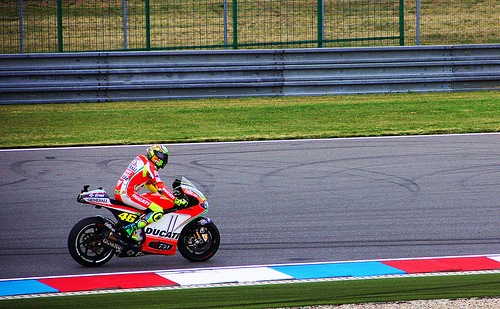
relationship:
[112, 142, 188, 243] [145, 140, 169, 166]
motorcyclist wearing helmet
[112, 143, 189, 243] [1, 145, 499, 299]
racer riding on raceway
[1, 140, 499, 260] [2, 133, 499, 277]
tire marks on track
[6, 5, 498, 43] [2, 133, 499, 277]
fence next to track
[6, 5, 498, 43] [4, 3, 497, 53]
fence next to field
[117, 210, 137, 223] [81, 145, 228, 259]
number on motorcycle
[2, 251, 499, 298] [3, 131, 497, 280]
buffer next to racetrack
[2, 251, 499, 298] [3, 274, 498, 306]
buffer next to infield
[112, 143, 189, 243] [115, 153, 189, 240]
racer dressed in clothing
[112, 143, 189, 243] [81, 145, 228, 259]
racer on motorcycle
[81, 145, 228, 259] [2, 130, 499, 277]
motorcycle heading down straightaway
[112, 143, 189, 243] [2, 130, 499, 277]
racer heading down straightaway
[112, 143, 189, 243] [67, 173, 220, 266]
racer riding bike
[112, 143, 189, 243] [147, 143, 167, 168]
racer wearing helmet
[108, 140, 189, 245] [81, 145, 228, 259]
man riding a motorcycle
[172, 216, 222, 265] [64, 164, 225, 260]
front wheel of motorcycle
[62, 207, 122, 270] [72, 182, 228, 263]
rear wheel of motorcycle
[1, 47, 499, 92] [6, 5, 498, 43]
guardrail next to fence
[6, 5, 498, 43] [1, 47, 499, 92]
fence in back of guardrail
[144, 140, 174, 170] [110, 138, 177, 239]
helmet worn by motorcyclist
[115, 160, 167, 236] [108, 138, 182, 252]
outfit worn by man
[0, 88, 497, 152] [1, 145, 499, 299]
grass on side of raceway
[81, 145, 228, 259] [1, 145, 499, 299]
motorcycle runs on a raceway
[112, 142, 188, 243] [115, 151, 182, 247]
motorcyclist wears suit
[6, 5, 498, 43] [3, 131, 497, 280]
fence beside racetrack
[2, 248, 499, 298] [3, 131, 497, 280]
line on side of racetrack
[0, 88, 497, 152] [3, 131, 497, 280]
grass on side of racetrack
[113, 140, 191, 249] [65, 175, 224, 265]
driver racing motorbike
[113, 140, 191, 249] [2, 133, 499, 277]
driver racing on track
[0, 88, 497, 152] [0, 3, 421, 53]
grass in front of fence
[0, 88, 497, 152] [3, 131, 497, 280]
grass behind racetrack